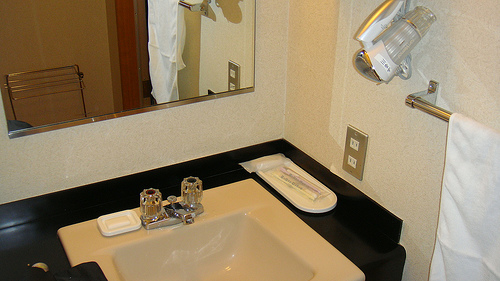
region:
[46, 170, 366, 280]
THE SINK IS OFF WHITE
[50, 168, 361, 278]
THE SINK IS SQUARE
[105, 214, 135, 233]
THE SOAP IS WHITE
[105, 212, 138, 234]
THE SOAP IS IN A DISH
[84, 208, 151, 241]
THE SOAP DISH IS WHITE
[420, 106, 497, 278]
THE TOWEL IS WHITE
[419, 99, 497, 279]
THE TOWEL IS HANGING NEXT TO THE SINK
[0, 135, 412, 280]
THE COUNTER IS BLACK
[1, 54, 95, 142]
THE LUGGAGE RACK IS REFLECTING IN THE MIRROR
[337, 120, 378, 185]
THE OUTLET IS SILVER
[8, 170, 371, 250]
White sink inlayed on a black counter top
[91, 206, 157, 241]
Small white soap in a soap dish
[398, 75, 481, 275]
White towel hanging on metal rack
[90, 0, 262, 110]
Mirror in the bathroom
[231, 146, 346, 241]
Unopened toiletries on the counter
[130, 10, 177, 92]
Towel has several creases from being folded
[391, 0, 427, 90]
Appliance hanging on the wall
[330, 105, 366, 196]
Outlet with stainless steel cover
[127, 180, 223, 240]
Chrome faucet with clear plastic handles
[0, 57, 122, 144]
Small towel rack visible in mirror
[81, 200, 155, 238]
Bar of soap on soap dish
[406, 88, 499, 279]
white towel hangs on towel rack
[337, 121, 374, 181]
Two hole outlet on wall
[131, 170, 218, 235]
faucet handles on sink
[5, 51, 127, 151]
A towel rack reflected in mirror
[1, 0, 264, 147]
A mirror above the sink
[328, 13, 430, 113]
a cup dispenser on the wall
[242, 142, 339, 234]
a white tray with something on it by the wall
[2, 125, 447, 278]
a black countertop and white sink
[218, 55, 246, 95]
reflection of the outlet in mirror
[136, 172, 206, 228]
Couple of water taps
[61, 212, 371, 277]
White, shiny sink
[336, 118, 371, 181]
Pair of electric sockets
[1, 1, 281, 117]
Wide wall mirror with reflecitons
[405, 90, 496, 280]
Towel hanging down the wall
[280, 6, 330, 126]
Cream shade of the wall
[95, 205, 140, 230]
Cake of white soap in a container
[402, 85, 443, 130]
Wall bar for hanging clothing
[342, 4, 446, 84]
Bottle on a holder on the wall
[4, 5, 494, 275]
Section of a washroom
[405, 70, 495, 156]
Chrome towel rack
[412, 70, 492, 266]
White towel hanging on chrome towel rack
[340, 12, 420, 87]
Appliance hanging on wall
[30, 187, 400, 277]
White sink and black counter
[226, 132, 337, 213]
New unopened toiletries on counter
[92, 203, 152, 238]
White soap in soap dish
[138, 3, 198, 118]
Creased towel hanging on rack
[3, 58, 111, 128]
Small towel rack in bathroom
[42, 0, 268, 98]
Mirror in bathroom